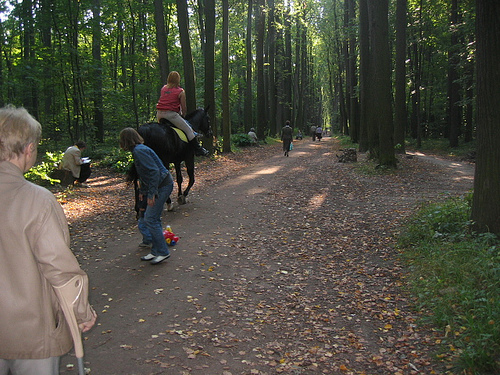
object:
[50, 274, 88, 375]
crutch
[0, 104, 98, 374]
woman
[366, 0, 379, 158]
trunks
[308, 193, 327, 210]
sunlight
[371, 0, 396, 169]
trunk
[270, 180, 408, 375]
leaves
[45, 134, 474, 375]
road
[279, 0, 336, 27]
light shining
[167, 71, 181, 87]
hair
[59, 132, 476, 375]
path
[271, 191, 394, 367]
dry leaves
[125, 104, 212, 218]
horse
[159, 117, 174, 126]
saddle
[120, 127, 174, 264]
people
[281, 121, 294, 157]
people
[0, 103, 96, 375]
people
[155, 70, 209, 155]
people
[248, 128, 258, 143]
people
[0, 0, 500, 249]
woods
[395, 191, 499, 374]
grass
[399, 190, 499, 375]
plants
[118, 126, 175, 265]
woman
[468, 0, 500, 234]
trees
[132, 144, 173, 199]
blue shirt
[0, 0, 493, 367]
photo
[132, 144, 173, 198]
jacket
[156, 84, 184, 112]
shirt